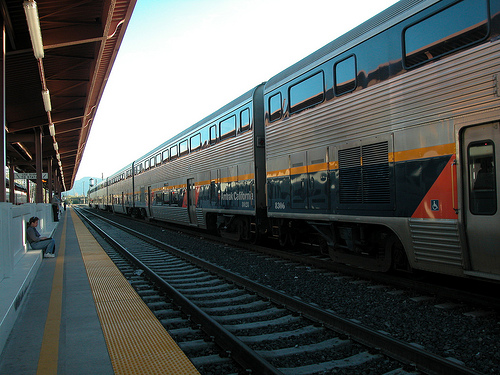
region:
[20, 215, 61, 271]
Man sitting on bench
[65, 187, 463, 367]
Train tracks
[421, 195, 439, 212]
Handicap symbol on side of train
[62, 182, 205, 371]
Yellow caution line next to train tracks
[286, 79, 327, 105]
One of many windows on train car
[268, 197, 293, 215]
Number one hundred thirty six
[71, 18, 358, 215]
Sky completely covered in clouds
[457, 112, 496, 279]
Door allowing access into train car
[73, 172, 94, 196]
Mountains off in the distance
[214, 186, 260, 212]
Name of the train is Amtrak California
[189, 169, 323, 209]
reflections on the shinny side of train cars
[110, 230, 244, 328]
railroad rails and ties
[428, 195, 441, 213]
a handicap accessible sign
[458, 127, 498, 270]
the door on a train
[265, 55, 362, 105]
windows on the side of train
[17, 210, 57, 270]
a person sitting on a bench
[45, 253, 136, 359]
yellow paint on a train loading platform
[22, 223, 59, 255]
a person dressed in grey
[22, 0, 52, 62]
a tube fluorescent light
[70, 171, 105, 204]
a mountain in the distance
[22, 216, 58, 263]
Man sitting on bench.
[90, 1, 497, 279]
Passenger train at station.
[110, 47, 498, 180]
Passenger windows on train.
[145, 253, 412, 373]
Metal railroad tracks.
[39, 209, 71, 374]
Yellow line painted on platform.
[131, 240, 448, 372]
Gravel around train tracks.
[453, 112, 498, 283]
Door on side of train.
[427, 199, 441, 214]
Blue and white handicap sign.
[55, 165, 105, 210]
Mountain in the far distance.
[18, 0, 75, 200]
White lights on roof.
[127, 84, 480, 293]
SILVER PASSENGER TRAIN AT STATION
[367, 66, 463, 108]
SILVER RIDGES ON TRAIN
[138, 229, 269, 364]
CONCRETE RAILROAD TIES ON TRACK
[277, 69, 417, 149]
ROW OF WINDOWS ON TRAIN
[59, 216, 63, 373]
YELLOW LINE ON PLATFORM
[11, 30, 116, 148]
BROWN AWNING OVER PLATFORM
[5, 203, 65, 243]
BENCH ON LEFT PLATFORM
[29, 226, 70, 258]
PERSON SITTING ON BENCH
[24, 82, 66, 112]
LIGHTS ON STATION OVERHANG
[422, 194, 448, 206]
HANDICAP STICKER ON TRAIN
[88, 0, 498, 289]
large train on tracks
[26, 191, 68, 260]
people at train platform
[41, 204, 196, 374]
yellow paint on platform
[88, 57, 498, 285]
train is silver, yellow, orange, and blue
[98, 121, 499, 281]
doors are train are metal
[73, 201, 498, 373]
two sets of metal tracks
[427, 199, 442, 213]
blue handicap sign near door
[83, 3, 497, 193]
long row of tinted windows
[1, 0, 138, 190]
roof hangs over platform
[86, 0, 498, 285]
Train has two floors